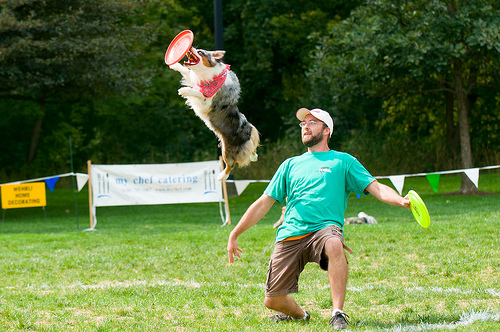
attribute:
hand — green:
[397, 190, 412, 209]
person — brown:
[359, 152, 466, 206]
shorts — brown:
[263, 230, 345, 297]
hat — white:
[289, 98, 349, 140]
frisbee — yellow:
[405, 185, 450, 237]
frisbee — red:
[161, 28, 196, 65]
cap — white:
[277, 100, 337, 137]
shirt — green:
[262, 148, 372, 243]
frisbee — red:
[397, 186, 443, 232]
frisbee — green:
[404, 191, 431, 229]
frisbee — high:
[146, 21, 198, 68]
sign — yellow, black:
[2, 181, 46, 208]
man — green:
[227, 107, 410, 328]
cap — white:
[295, 101, 332, 135]